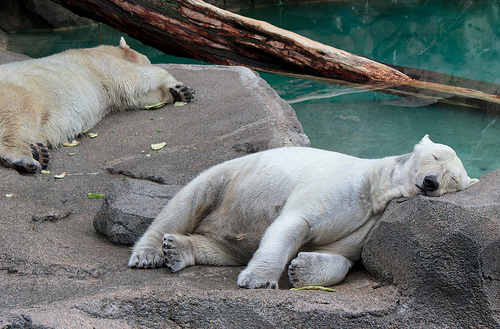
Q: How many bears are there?
A: Two.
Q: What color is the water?
A: Green.